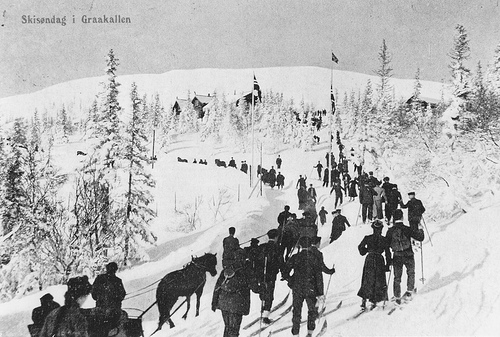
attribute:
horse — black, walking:
[156, 252, 216, 327]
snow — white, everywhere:
[5, 65, 499, 117]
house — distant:
[192, 95, 219, 122]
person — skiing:
[287, 236, 328, 336]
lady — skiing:
[359, 220, 391, 314]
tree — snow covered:
[111, 82, 159, 268]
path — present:
[141, 187, 290, 300]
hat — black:
[299, 236, 312, 248]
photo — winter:
[1, 2, 499, 335]